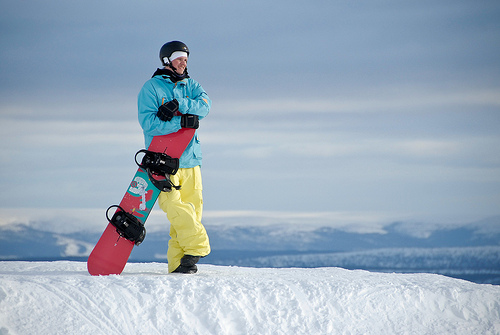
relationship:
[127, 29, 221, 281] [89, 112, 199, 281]
man has board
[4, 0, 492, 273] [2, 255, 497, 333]
sky behind snow